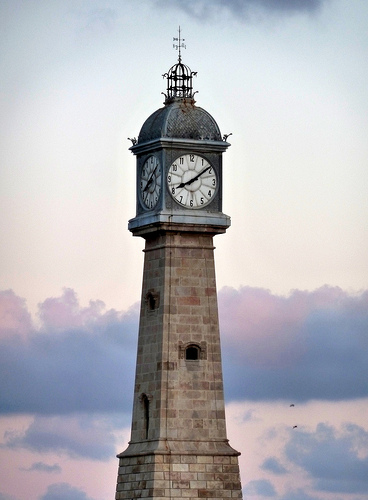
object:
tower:
[127, 66, 251, 481]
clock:
[166, 148, 218, 208]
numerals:
[188, 155, 196, 166]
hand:
[175, 169, 196, 197]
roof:
[143, 95, 224, 142]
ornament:
[161, 62, 198, 109]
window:
[175, 338, 212, 384]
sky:
[12, 65, 122, 230]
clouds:
[33, 282, 106, 327]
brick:
[176, 262, 201, 281]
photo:
[47, 19, 331, 491]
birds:
[287, 415, 300, 433]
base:
[133, 212, 229, 249]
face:
[176, 162, 209, 194]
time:
[165, 148, 219, 205]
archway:
[127, 388, 154, 408]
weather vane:
[139, 52, 216, 109]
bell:
[157, 57, 252, 169]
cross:
[171, 32, 188, 60]